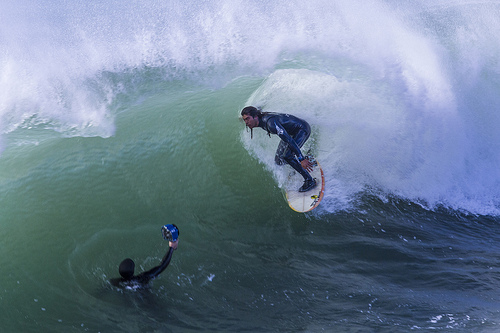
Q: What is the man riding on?
A: Surfboard.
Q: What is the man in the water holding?
A: Helmet.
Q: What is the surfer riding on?
A: Wave.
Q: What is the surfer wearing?
A: Wetsuit.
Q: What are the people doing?
A: Surfing.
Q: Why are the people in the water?
A: To surf.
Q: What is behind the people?
A: A wave.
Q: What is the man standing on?
A: A surfboard.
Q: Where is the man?
A: Under the wave.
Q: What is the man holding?
A: A helmet.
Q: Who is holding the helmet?
A: The left man.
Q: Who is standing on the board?
A: The right surfer.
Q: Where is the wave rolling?
A: Forward.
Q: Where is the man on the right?
A: On the surfboard.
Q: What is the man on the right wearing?
A: A wet suit.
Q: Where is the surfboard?
A: Under the man on the right.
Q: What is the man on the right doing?
A: Surfing.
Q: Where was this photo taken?
A: The ocean.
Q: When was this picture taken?
A: Day time.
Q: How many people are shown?
A: Two.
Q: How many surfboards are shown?
A: One.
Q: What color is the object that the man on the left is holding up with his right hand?
A: Blue.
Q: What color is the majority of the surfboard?
A: White.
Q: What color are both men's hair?
A: Black.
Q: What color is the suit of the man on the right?
A: Blue.